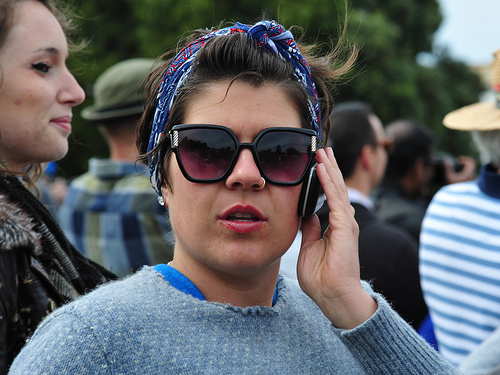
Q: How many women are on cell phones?
A: One.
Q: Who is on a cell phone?
A: The woman in the front.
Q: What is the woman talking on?
A: A cell phone.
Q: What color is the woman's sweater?
A: Blue.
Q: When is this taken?
A: Daytime.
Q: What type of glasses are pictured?
A: Sunglasses.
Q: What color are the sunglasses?
A: Black.